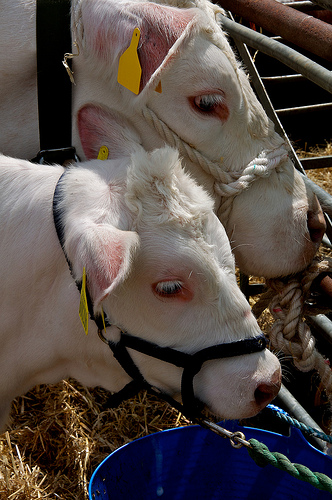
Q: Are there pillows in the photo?
A: No, there are no pillows.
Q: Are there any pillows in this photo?
A: No, there are no pillows.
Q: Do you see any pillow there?
A: No, there are no pillows.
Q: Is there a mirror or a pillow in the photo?
A: No, there are no pillows or mirrors.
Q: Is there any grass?
A: Yes, there is grass.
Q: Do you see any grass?
A: Yes, there is grass.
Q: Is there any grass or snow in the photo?
A: Yes, there is grass.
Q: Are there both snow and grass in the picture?
A: No, there is grass but no snow.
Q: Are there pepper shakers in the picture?
A: No, there are no pepper shakers.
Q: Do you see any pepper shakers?
A: No, there are no pepper shakers.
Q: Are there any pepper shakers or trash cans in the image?
A: No, there are no pepper shakers or trash cans.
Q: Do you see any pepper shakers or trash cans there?
A: No, there are no pepper shakers or trash cans.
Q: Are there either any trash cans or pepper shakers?
A: No, there are no pepper shakers or trash cans.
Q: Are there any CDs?
A: No, there are no cds.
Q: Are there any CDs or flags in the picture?
A: No, there are no CDs or flags.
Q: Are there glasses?
A: No, there are no glasses.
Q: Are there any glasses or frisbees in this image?
A: No, there are no glasses or frisbees.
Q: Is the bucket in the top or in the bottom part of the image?
A: The bucket is in the bottom of the image.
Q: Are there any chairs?
A: No, there are no chairs.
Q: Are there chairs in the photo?
A: No, there are no chairs.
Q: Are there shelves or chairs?
A: No, there are no chairs or shelves.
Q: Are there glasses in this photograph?
A: No, there are no glasses.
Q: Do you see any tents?
A: No, there are no tents.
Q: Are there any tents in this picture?
A: No, there are no tents.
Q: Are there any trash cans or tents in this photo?
A: No, there are no tents or trash cans.